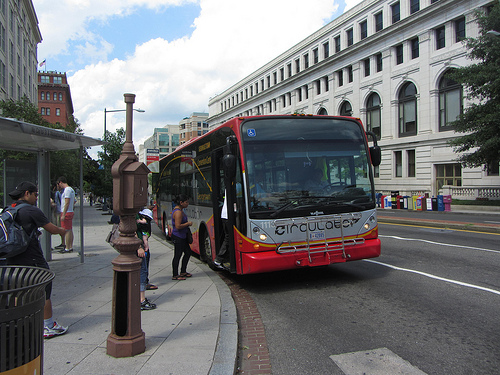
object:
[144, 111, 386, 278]
bus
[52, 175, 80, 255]
man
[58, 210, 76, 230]
shorts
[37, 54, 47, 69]
flag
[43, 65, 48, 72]
flag pole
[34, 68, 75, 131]
building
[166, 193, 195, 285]
woman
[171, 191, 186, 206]
hair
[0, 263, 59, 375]
garbage can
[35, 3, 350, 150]
sky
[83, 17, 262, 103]
clouds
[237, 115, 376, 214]
windshield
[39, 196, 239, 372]
sidewalk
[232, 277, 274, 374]
design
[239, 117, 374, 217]
front window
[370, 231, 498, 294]
paint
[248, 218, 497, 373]
road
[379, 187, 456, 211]
newspaper boxes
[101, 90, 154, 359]
pole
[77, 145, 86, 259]
post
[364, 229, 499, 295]
line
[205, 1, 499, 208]
building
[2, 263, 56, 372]
trash can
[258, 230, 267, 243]
headlight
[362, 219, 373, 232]
headlight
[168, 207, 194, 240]
blouse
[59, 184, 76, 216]
t-shirt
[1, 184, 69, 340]
man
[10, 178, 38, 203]
baseball cap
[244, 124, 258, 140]
symbol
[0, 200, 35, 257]
back pack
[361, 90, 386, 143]
window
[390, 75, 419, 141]
window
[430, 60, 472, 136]
window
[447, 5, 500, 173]
pine tree